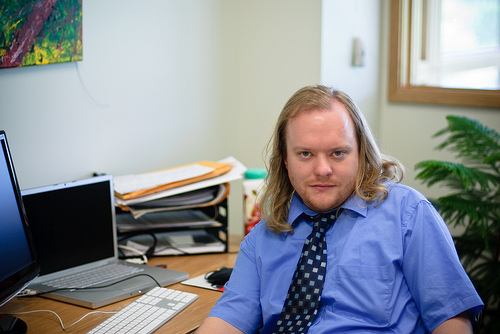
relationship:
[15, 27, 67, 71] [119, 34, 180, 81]
picture on wall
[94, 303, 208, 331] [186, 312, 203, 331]
keyborad on desk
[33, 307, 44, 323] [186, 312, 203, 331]
wooden top desk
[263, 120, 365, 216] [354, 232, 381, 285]
man in shirt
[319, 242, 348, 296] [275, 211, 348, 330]
blue patterned blue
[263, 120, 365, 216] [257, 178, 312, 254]
man long hair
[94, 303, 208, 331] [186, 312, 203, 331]
keyboard on desk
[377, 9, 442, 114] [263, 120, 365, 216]
window behind man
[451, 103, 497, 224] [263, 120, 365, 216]
plant behind man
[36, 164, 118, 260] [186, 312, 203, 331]
monitor on desk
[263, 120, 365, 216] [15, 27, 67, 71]
man posting picture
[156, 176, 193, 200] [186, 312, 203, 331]
files on desk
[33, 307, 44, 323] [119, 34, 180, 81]
wooden frame wall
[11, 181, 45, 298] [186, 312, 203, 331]
computer monitor desk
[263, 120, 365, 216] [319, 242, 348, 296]
man in blue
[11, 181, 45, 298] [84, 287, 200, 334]
computer screen keyborad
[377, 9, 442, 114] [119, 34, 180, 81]
window on wall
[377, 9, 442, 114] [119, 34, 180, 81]
window by wall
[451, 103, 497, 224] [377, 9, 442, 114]
plant by window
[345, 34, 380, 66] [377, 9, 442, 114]
thermostat by window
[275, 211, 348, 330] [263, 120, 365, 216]
blue on man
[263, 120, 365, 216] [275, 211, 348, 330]
man in blue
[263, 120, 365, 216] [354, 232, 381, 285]
man blue shirt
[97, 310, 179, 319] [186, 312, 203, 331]
white keybord desk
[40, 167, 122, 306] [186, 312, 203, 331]
laptop on desk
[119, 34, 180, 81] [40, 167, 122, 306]
wall behind laptop